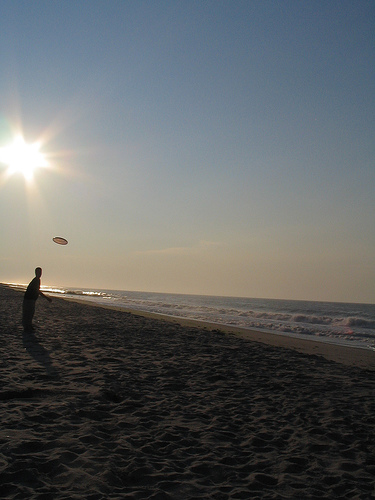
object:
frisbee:
[52, 236, 68, 246]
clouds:
[0, 1, 374, 306]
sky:
[2, 1, 374, 303]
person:
[21, 266, 53, 329]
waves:
[132, 303, 374, 340]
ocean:
[0, 281, 375, 318]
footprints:
[0, 281, 374, 497]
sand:
[0, 281, 375, 499]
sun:
[1, 132, 48, 182]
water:
[49, 283, 375, 321]